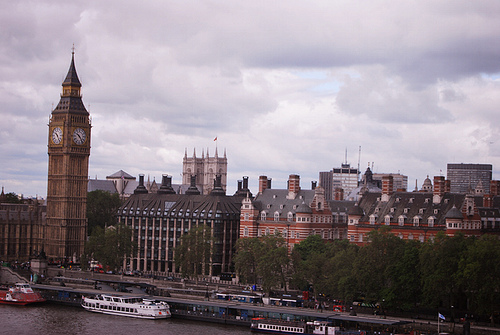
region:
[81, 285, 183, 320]
a long white ferry boat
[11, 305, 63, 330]
a body of dark water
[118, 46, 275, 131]
a white fluffy cloud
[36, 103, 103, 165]
a clock in a tower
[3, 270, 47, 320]
a red and white boat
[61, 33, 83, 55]
a weather vane on top of the tower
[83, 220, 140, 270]
a tree near a bridge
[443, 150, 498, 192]
a gray building in the distance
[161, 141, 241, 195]
twin buildings in the background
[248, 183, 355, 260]
a building with turrets and windows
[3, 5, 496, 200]
Grey clouds in the sky.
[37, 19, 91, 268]
Large church tower with a clock.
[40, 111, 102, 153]
Two clock faces in the tower.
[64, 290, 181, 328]
White boat in the river.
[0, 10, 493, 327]
Photo taken during the day.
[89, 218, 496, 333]
Trees along the road.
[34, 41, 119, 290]
Photo taken at 10:25 in the morning.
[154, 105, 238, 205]
Large building with a flag in the background.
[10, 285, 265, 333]
River with boats in it.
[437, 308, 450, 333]
Blue and white flag.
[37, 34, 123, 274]
big ben tower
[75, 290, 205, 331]
barge on side of river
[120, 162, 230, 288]
building on side of pier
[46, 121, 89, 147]
clock faces on tower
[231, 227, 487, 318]
treese on side of river bank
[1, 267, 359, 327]
boats moored at river bank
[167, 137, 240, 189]
top of steeples of cathedral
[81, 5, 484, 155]
clouds in the sky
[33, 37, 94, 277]
tower with clocks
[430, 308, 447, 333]
flag flying on river bank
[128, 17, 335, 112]
the sky is cloudy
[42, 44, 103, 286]
the tower is orange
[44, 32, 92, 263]
the tower is tall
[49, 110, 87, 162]
the clock is round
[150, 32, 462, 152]
the clouds are dark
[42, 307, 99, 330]
the water has ripples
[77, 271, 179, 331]
the ship is white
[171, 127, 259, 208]
the building is pointy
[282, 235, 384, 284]
the trees are green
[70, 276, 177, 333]
the boat is floating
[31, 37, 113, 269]
large building with clock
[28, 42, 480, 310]
a lot of buildings by a boat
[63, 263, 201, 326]
white boat on water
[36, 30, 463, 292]
a lot of buildings with spikey tops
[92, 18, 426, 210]
cloudy sky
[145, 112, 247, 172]
flag on top of a building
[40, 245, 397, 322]
busy road way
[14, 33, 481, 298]
view of a city by water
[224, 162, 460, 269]
red buildings with round towers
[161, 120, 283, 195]
building displaying a flag